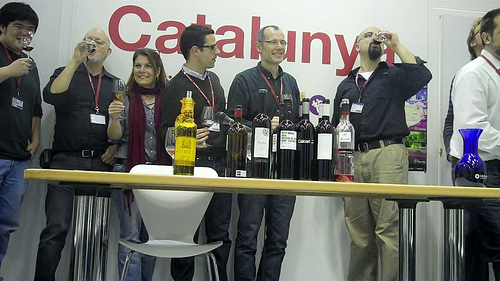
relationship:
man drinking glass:
[323, 18, 435, 278] [363, 30, 391, 43]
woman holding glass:
[107, 47, 171, 280] [256, 21, 333, 56]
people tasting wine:
[8, 15, 499, 225] [328, 92, 359, 175]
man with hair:
[154, 20, 236, 279] [179, 19, 213, 62]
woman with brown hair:
[107, 47, 171, 280] [132, 42, 164, 61]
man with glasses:
[32, 27, 124, 281] [78, 34, 110, 51]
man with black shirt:
[32, 27, 124, 281] [57, 64, 114, 144]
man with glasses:
[32, 27, 124, 281] [74, 26, 145, 48]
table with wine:
[20, 164, 499, 279] [219, 99, 251, 179]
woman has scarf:
[117, 48, 167, 278] [125, 83, 172, 214]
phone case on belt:
[38, 145, 48, 167] [53, 140, 110, 162]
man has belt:
[49, 38, 105, 171] [53, 140, 110, 162]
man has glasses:
[226, 23, 300, 279] [195, 41, 221, 61]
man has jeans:
[226, 23, 300, 279] [153, 144, 234, 272]